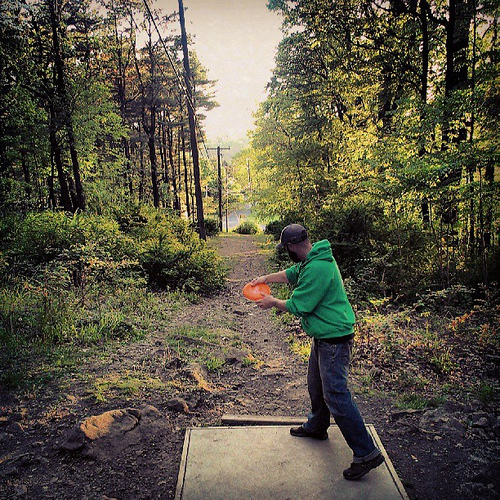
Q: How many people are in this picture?
A: One.